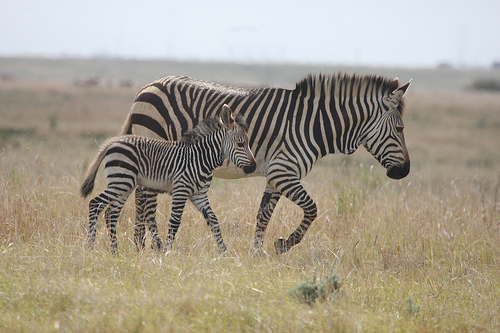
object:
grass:
[4, 78, 494, 333]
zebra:
[116, 70, 417, 254]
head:
[352, 78, 412, 180]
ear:
[389, 71, 422, 105]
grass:
[408, 197, 458, 264]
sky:
[171, 16, 215, 49]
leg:
[160, 171, 196, 249]